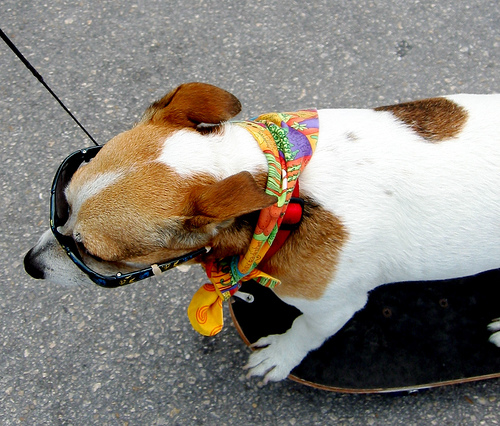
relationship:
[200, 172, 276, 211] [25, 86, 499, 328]
ear of dog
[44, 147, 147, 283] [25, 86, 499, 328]
sunglasses on dog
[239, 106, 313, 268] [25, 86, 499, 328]
bandana on dog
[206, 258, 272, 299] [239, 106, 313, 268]
knot on bandana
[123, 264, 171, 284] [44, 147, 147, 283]
design on sunglasses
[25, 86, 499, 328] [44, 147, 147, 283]
dog wearing glasses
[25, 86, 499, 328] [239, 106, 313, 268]
dog wearing bandana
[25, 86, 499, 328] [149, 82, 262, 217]
dog has ears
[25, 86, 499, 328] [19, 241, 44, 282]
dog has nose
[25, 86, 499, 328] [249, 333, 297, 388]
dog has paws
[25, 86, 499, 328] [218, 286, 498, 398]
dog riding skateboard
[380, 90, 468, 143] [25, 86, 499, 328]
spots on dog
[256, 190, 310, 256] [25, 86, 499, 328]
leash on dog